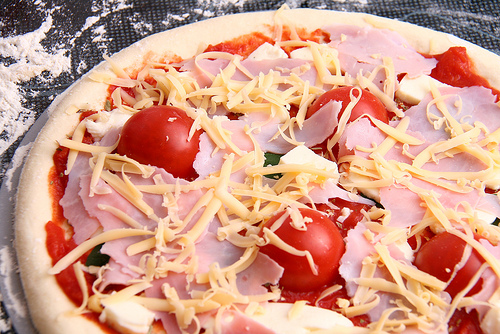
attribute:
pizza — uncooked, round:
[10, 3, 499, 328]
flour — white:
[0, 16, 70, 99]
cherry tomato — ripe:
[112, 98, 209, 179]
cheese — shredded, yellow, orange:
[107, 59, 296, 103]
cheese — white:
[93, 290, 156, 333]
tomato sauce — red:
[430, 47, 479, 89]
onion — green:
[85, 243, 106, 263]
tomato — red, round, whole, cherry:
[254, 203, 349, 295]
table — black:
[4, 1, 113, 64]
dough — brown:
[11, 101, 60, 326]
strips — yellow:
[149, 67, 313, 104]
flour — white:
[92, 24, 111, 46]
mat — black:
[19, 3, 164, 33]